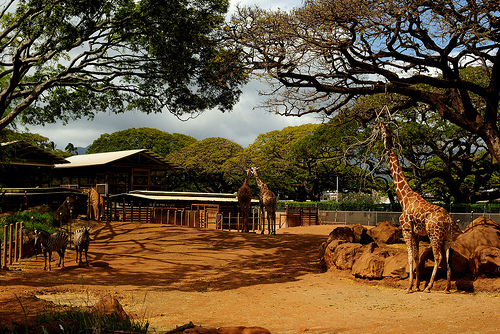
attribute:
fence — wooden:
[138, 186, 253, 251]